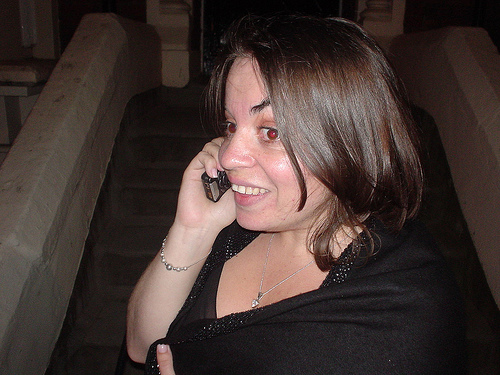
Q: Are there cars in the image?
A: No, there are no cars.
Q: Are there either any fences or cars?
A: No, there are no cars or fences.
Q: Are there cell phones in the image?
A: Yes, there is a cell phone.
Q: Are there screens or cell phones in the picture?
A: Yes, there is a cell phone.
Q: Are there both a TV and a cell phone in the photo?
A: No, there is a cell phone but no televisions.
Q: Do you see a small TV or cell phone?
A: Yes, there is a small cell phone.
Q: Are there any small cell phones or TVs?
A: Yes, there is a small cell phone.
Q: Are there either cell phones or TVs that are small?
A: Yes, the cell phone is small.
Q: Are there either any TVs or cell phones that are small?
A: Yes, the cell phone is small.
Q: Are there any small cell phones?
A: Yes, there is a small cell phone.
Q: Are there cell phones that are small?
A: Yes, there is a cell phone that is small.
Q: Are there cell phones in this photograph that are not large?
A: Yes, there is a small cell phone.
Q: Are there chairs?
A: No, there are no chairs.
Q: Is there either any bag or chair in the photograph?
A: No, there are no chairs or bags.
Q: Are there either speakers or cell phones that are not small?
A: No, there is a cell phone but it is small.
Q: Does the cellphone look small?
A: Yes, the cellphone is small.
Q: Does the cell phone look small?
A: Yes, the cell phone is small.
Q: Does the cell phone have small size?
A: Yes, the cell phone is small.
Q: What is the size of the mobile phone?
A: The mobile phone is small.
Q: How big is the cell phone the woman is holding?
A: The mobile phone is small.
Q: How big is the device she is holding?
A: The mobile phone is small.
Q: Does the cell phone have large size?
A: No, the cell phone is small.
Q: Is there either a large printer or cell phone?
A: No, there is a cell phone but it is small.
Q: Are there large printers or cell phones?
A: No, there is a cell phone but it is small.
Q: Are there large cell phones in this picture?
A: No, there is a cell phone but it is small.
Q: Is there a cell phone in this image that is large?
A: No, there is a cell phone but it is small.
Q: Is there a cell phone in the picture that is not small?
A: No, there is a cell phone but it is small.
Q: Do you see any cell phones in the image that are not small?
A: No, there is a cell phone but it is small.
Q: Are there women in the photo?
A: Yes, there is a woman.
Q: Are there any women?
A: Yes, there is a woman.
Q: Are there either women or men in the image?
A: Yes, there is a woman.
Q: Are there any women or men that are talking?
A: Yes, the woman is talking.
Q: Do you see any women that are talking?
A: Yes, there is a woman that is talking.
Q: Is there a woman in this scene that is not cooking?
A: Yes, there is a woman that is talking.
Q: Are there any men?
A: No, there are no men.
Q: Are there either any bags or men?
A: No, there are no men or bags.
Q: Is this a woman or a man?
A: This is a woman.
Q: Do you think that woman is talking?
A: Yes, the woman is talking.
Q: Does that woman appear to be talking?
A: Yes, the woman is talking.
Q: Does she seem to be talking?
A: Yes, the woman is talking.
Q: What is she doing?
A: The woman is talking.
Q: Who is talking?
A: The woman is talking.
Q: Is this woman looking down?
A: No, the woman is talking.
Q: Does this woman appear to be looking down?
A: No, the woman is talking.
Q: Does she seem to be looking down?
A: No, the woman is talking.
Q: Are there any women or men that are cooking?
A: No, there is a woman but she is talking.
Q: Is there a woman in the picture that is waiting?
A: No, there is a woman but she is talking.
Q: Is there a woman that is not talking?
A: No, there is a woman but she is talking.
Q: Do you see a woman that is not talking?
A: No, there is a woman but she is talking.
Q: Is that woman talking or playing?
A: The woman is talking.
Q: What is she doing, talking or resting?
A: The woman is talking.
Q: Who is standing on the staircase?
A: The woman is standing on the staircase.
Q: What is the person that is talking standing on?
A: The woman is standing on the staircase.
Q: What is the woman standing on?
A: The woman is standing on the staircase.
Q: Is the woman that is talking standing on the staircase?
A: Yes, the woman is standing on the staircase.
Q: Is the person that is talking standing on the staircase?
A: Yes, the woman is standing on the staircase.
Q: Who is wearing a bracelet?
A: The woman is wearing a bracelet.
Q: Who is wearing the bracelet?
A: The woman is wearing a bracelet.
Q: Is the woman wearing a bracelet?
A: Yes, the woman is wearing a bracelet.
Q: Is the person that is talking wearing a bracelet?
A: Yes, the woman is wearing a bracelet.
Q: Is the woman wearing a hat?
A: No, the woman is wearing a bracelet.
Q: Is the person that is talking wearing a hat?
A: No, the woman is wearing a bracelet.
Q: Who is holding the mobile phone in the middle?
A: The woman is holding the mobile phone.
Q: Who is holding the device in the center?
A: The woman is holding the mobile phone.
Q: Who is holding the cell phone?
A: The woman is holding the mobile phone.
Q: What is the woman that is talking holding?
A: The woman is holding the mobile phone.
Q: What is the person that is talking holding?
A: The woman is holding the mobile phone.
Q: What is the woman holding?
A: The woman is holding the mobile phone.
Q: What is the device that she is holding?
A: The device is a cell phone.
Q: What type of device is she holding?
A: The woman is holding the mobile phone.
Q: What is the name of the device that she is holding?
A: The device is a cell phone.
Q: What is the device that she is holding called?
A: The device is a cell phone.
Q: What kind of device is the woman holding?
A: The woman is holding the mobile phone.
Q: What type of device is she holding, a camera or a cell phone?
A: The woman is holding a cell phone.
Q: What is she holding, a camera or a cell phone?
A: The woman is holding a cell phone.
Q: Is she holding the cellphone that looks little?
A: Yes, the woman is holding the mobile phone.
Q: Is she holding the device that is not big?
A: Yes, the woman is holding the mobile phone.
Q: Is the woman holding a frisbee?
A: No, the woman is holding the mobile phone.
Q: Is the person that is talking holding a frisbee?
A: No, the woman is holding the mobile phone.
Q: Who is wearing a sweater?
A: The woman is wearing a sweater.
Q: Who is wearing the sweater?
A: The woman is wearing a sweater.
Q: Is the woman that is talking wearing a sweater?
A: Yes, the woman is wearing a sweater.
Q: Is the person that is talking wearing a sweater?
A: Yes, the woman is wearing a sweater.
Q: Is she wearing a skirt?
A: No, the woman is wearing a sweater.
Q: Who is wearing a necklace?
A: The woman is wearing a necklace.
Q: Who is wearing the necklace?
A: The woman is wearing a necklace.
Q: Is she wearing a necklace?
A: Yes, the woman is wearing a necklace.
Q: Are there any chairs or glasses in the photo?
A: No, there are no glasses or chairs.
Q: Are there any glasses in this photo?
A: No, there are no glasses.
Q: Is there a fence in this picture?
A: No, there are no fences.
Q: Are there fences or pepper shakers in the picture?
A: No, there are no fences or pepper shakers.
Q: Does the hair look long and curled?
A: Yes, the hair is long and curled.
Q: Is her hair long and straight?
A: No, the hair is long but curled.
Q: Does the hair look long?
A: Yes, the hair is long.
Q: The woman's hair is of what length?
A: The hair is long.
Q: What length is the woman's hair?
A: The hair is long.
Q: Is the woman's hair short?
A: No, the hair is long.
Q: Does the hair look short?
A: No, the hair is long.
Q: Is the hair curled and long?
A: Yes, the hair is curled and long.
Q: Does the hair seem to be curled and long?
A: Yes, the hair is curled and long.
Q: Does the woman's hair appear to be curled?
A: Yes, the hair is curled.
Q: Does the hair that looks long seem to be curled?
A: Yes, the hair is curled.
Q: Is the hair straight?
A: No, the hair is curled.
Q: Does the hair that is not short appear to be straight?
A: No, the hair is curled.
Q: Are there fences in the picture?
A: No, there are no fences.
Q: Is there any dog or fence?
A: No, there are no fences or dogs.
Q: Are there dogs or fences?
A: No, there are no fences or dogs.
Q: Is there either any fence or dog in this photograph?
A: No, there are no fences or dogs.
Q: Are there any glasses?
A: No, there are no glasses.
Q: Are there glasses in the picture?
A: No, there are no glasses.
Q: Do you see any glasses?
A: No, there are no glasses.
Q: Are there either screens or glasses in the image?
A: No, there are no glasses or screens.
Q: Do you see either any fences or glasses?
A: No, there are no glasses or fences.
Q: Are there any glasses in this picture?
A: No, there are no glasses.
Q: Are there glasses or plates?
A: No, there are no glasses or plates.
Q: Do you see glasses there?
A: No, there are no glasses.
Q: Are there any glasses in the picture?
A: No, there are no glasses.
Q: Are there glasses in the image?
A: No, there are no glasses.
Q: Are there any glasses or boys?
A: No, there are no glasses or boys.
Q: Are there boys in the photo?
A: No, there are no boys.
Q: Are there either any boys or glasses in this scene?
A: No, there are no boys or glasses.